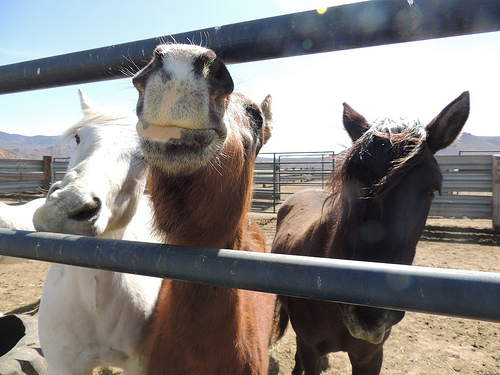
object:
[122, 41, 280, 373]
horse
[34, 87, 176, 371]
horse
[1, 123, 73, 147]
mountains